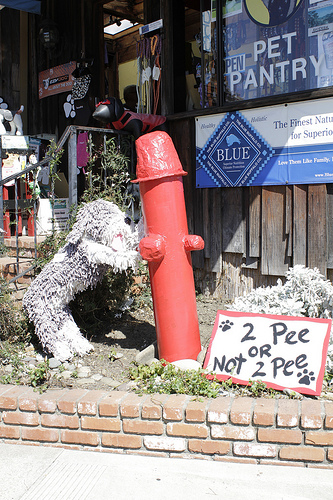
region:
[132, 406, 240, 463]
Red and white bricks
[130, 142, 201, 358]
A sculpture of a hydrant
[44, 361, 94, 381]
Rocks and pebbles on the ground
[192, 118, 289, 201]
A blue and white sign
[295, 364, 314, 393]
A painted paw print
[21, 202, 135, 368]
A gray and white sheepdog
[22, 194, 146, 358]
This dog is not real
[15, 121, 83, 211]
Black wrought iron handrail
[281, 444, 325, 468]
one red brick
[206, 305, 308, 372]
A handpainted sign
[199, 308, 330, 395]
A sign with a pun and puppy paw prints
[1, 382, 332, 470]
Brick edging between a sidewalk and a garden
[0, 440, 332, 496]
The edge of concrete sidewalk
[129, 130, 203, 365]
A sculpture of a red fire hydrant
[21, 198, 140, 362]
A sculpture of a gray and white dog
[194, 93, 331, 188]
A blue and white advertising sign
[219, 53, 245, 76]
Part of an open sign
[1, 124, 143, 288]
Metal railing for stairs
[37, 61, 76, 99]
A red, white and black advertising sign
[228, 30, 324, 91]
White words painted on a shop window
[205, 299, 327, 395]
red and white sign on sidewalk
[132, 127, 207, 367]
red sculpture of fire hydrant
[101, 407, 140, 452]
red bricks on wall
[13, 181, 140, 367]
grey and white stuffed dog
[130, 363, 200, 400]
small plants growing in front of building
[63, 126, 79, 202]
grey metal guard rail post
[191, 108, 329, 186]
sign hanging on side of building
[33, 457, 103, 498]
small stone grooves in sidewalk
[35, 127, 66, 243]
green vines growing on guard rail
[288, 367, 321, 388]
paw print design on sign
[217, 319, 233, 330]
a black paw print on a white background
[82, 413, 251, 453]
a section of a brick wall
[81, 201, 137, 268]
the face of a toy dog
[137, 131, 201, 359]
a fake fire hydrant for decoration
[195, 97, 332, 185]
a wall advertisement for Blue Buffalo pet food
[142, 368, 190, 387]
some green plants growing in gravel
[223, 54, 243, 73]
part of an OPEN sign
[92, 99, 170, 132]
a black balloon wiener dog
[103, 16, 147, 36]
a light viewed through an open door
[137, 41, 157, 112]
lanyards for sale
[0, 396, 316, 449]
a red brick stoop.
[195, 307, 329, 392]
a sign says 2 pee or not 2 pee.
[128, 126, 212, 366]
a painted red fire hydrant.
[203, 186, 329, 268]
wood on a building.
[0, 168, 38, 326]
a brick stair case.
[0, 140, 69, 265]
a black metal railing.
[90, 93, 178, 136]
a red and black toy animal.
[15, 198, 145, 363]
a white doggy stuffed animal.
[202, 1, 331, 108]
a window says pen pet pantry.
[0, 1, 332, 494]
a neighborhood store.